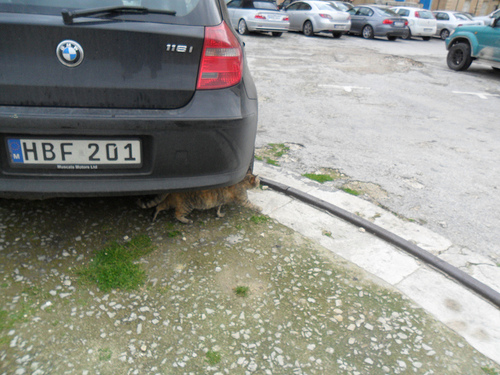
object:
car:
[1, 0, 259, 199]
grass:
[84, 225, 156, 282]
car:
[286, 1, 355, 45]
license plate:
[1, 125, 155, 174]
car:
[447, 16, 499, 85]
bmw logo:
[52, 34, 93, 71]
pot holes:
[350, 183, 387, 200]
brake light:
[195, 15, 246, 100]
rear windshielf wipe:
[56, 6, 191, 36]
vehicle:
[220, 2, 295, 46]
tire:
[234, 14, 250, 38]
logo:
[54, 37, 88, 66]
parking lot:
[266, 68, 498, 322]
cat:
[133, 171, 260, 223]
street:
[328, 81, 443, 203]